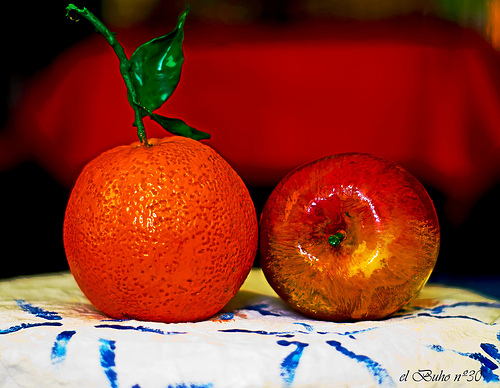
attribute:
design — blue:
[1, 292, 186, 385]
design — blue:
[219, 318, 394, 386]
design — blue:
[231, 300, 283, 317]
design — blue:
[402, 298, 484, 327]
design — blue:
[423, 330, 484, 384]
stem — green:
[327, 229, 344, 248]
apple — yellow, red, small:
[258, 150, 442, 323]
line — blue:
[325, 338, 396, 386]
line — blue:
[275, 337, 310, 386]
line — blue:
[216, 325, 309, 341]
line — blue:
[292, 319, 312, 329]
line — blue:
[315, 322, 378, 341]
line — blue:
[92, 322, 187, 336]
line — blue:
[97, 335, 120, 385]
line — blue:
[50, 330, 75, 365]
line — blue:
[0, 318, 61, 335]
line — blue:
[11, 296, 61, 319]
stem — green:
[63, 1, 150, 143]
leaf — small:
[132, 98, 212, 141]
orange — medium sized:
[57, 1, 259, 321]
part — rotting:
[297, 273, 358, 316]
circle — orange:
[63, 134, 257, 319]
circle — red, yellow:
[257, 151, 440, 320]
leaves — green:
[127, 9, 212, 139]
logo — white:
[395, 366, 484, 382]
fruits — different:
[64, 132, 442, 322]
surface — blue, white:
[1, 267, 498, 382]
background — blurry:
[4, 3, 497, 293]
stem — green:
[73, 4, 143, 144]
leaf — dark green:
[121, 9, 201, 125]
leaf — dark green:
[146, 105, 213, 143]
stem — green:
[324, 225, 342, 255]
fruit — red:
[257, 145, 446, 330]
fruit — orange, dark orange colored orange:
[62, 132, 257, 322]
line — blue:
[275, 348, 305, 385]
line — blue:
[325, 337, 388, 386]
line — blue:
[318, 323, 376, 337]